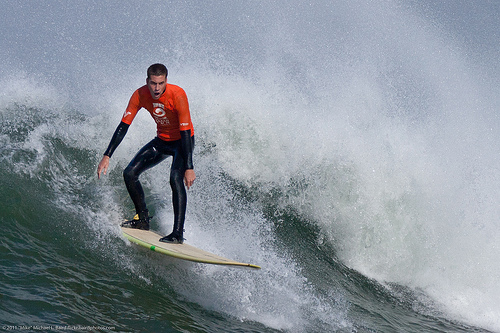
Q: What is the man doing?
A: Surfing.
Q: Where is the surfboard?
A: Under the man.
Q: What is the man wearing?
A: A black bodysuit.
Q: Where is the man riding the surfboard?
A: In the ocean.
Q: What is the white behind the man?
A: Ocean wave mist.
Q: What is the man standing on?
A: A surfboard.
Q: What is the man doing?
A: Surfing in the ocean.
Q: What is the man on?
A: A white surfboard.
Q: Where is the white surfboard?
A: In the water.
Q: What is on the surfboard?
A: A wet male surfer.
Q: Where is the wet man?
A: In the ocean.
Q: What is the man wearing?
A: An orange and black wetsuit.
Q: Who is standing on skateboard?
A: A man.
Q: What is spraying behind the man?
A: The water.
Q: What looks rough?
A: A wave.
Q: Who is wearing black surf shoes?
A: A man.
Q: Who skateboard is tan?
A: A man.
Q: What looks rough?
A: The water.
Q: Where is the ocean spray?
A: On the wave.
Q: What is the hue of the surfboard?
A: Beige and green.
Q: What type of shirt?
A: Long sleeved.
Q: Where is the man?
A: On the surfboard.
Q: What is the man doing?
A: Surfing.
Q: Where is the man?
A: In the ocean.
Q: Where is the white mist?
A: On top of wave.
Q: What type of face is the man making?
A: Surprised.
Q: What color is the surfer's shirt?
A: Orange.